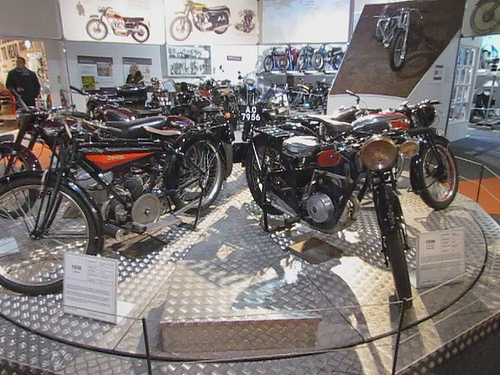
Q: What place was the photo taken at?
A: It was taken at the store.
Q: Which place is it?
A: It is a store.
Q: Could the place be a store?
A: Yes, it is a store.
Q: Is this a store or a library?
A: It is a store.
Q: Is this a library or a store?
A: It is a store.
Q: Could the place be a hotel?
A: No, it is a store.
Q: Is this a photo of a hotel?
A: No, the picture is showing a store.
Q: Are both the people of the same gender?
A: No, they are both male and female.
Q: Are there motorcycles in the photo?
A: Yes, there is a motorcycle.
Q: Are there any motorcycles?
A: Yes, there is a motorcycle.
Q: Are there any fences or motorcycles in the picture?
A: Yes, there is a motorcycle.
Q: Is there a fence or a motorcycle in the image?
A: Yes, there is a motorcycle.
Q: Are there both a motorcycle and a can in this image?
A: No, there is a motorcycle but no cans.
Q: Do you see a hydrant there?
A: No, there are no fire hydrants.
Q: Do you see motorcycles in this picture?
A: Yes, there is a motorcycle.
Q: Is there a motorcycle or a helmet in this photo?
A: Yes, there is a motorcycle.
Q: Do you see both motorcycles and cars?
A: No, there is a motorcycle but no cars.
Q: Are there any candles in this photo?
A: No, there are no candles.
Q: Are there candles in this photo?
A: No, there are no candles.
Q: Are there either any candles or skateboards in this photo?
A: No, there are no candles or skateboards.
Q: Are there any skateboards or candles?
A: No, there are no candles or skateboards.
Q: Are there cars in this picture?
A: No, there are no cars.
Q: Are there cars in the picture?
A: No, there are no cars.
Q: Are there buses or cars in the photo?
A: No, there are no cars or buses.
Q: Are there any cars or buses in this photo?
A: No, there are no cars or buses.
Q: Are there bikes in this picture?
A: Yes, there is a bike.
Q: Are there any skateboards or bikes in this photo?
A: Yes, there is a bike.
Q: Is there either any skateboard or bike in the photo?
A: Yes, there is a bike.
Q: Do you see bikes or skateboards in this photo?
A: Yes, there is a bike.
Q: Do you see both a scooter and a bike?
A: No, there is a bike but no scooters.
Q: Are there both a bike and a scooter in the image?
A: No, there is a bike but no scooters.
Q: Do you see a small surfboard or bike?
A: Yes, there is a small bike.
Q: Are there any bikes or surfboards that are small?
A: Yes, the bike is small.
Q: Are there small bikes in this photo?
A: Yes, there is a small bike.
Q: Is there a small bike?
A: Yes, there is a small bike.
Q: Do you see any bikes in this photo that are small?
A: Yes, there is a bike that is small.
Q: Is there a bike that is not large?
A: Yes, there is a small bike.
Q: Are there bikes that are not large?
A: Yes, there is a small bike.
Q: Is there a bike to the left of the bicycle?
A: Yes, there is a bike to the left of the bicycle.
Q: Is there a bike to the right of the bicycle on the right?
A: No, the bike is to the left of the bicycle.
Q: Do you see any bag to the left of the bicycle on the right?
A: No, there is a bike to the left of the bicycle.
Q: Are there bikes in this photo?
A: Yes, there is a bike.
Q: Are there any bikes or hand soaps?
A: Yes, there is a bike.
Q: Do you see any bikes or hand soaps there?
A: Yes, there is a bike.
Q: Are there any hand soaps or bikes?
A: Yes, there is a bike.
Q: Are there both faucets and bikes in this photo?
A: No, there is a bike but no faucets.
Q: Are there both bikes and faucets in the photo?
A: No, there is a bike but no faucets.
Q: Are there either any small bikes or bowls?
A: Yes, there is a small bike.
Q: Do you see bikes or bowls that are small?
A: Yes, the bike is small.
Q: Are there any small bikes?
A: Yes, there is a small bike.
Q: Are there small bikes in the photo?
A: Yes, there is a small bike.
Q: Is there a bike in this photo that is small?
A: Yes, there is a bike that is small.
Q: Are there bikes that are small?
A: Yes, there is a bike that is small.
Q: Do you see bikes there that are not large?
A: Yes, there is a small bike.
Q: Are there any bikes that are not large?
A: Yes, there is a small bike.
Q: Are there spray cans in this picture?
A: No, there are no spray cans.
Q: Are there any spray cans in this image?
A: No, there are no spray cans.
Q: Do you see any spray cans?
A: No, there are no spray cans.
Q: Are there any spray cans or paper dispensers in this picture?
A: No, there are no spray cans or paper dispensers.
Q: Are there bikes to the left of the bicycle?
A: Yes, there is a bike to the left of the bicycle.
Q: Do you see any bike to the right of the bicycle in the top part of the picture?
A: No, the bike is to the left of the bicycle.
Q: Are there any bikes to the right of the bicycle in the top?
A: No, the bike is to the left of the bicycle.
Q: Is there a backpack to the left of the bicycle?
A: No, there is a bike to the left of the bicycle.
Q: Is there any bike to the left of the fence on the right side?
A: Yes, there is a bike to the left of the fence.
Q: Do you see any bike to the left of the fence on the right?
A: Yes, there is a bike to the left of the fence.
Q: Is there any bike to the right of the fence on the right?
A: No, the bike is to the left of the fence.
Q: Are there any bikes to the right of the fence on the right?
A: No, the bike is to the left of the fence.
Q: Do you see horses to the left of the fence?
A: No, there is a bike to the left of the fence.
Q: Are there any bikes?
A: Yes, there is a bike.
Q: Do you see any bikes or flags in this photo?
A: Yes, there is a bike.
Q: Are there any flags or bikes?
A: Yes, there is a bike.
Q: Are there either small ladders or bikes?
A: Yes, there is a small bike.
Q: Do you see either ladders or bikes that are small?
A: Yes, the bike is small.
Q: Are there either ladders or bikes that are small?
A: Yes, the bike is small.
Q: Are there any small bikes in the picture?
A: Yes, there is a small bike.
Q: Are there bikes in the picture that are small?
A: Yes, there is a bike that is small.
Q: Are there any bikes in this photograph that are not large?
A: Yes, there is a small bike.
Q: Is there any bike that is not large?
A: Yes, there is a small bike.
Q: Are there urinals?
A: No, there are no urinals.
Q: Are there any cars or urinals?
A: No, there are no urinals or cars.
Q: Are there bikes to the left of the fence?
A: Yes, there is a bike to the left of the fence.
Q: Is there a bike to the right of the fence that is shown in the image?
A: No, the bike is to the left of the fence.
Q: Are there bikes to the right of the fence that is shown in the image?
A: No, the bike is to the left of the fence.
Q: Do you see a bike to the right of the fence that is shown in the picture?
A: No, the bike is to the left of the fence.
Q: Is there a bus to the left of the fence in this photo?
A: No, there is a bike to the left of the fence.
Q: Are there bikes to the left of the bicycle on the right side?
A: Yes, there is a bike to the left of the bicycle.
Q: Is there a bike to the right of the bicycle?
A: No, the bike is to the left of the bicycle.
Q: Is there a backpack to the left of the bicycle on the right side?
A: No, there is a bike to the left of the bicycle.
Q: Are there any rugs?
A: No, there are no rugs.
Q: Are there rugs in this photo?
A: No, there are no rugs.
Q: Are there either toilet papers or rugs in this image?
A: No, there are no rugs or toilet papers.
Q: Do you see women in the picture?
A: Yes, there is a woman.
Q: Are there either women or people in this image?
A: Yes, there is a woman.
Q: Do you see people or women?
A: Yes, there is a woman.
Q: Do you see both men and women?
A: Yes, there are both a woman and a man.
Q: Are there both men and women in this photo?
A: Yes, there are both a woman and a man.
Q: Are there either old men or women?
A: Yes, there is an old woman.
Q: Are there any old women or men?
A: Yes, there is an old woman.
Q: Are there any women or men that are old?
A: Yes, the woman is old.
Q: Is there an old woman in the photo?
A: Yes, there is an old woman.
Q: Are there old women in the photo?
A: Yes, there is an old woman.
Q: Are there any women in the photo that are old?
A: Yes, there is an old woman.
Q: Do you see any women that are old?
A: Yes, there is a woman that is old.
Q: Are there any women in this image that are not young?
A: Yes, there is a old woman.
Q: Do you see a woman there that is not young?
A: Yes, there is a old woman.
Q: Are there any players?
A: No, there are no players.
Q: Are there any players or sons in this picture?
A: No, there are no players or sons.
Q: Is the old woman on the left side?
A: Yes, the woman is on the left of the image.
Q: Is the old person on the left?
A: Yes, the woman is on the left of the image.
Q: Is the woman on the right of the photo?
A: No, the woman is on the left of the image.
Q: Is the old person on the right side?
A: No, the woman is on the left of the image.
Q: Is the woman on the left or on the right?
A: The woman is on the left of the image.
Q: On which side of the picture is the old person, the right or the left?
A: The woman is on the left of the image.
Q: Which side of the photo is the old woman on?
A: The woman is on the left of the image.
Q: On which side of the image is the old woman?
A: The woman is on the left of the image.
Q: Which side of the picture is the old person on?
A: The woman is on the left of the image.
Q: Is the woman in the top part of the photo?
A: Yes, the woman is in the top of the image.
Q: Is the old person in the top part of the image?
A: Yes, the woman is in the top of the image.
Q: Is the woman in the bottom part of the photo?
A: No, the woman is in the top of the image.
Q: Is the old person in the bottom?
A: No, the woman is in the top of the image.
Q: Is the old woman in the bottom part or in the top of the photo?
A: The woman is in the top of the image.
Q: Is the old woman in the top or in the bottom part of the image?
A: The woman is in the top of the image.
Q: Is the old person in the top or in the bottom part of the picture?
A: The woman is in the top of the image.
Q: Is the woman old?
A: Yes, the woman is old.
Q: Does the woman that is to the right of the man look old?
A: Yes, the woman is old.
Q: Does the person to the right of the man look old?
A: Yes, the woman is old.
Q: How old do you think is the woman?
A: The woman is old.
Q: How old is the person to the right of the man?
A: The woman is old.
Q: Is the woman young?
A: No, the woman is old.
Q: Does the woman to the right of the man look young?
A: No, the woman is old.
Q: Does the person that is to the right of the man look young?
A: No, the woman is old.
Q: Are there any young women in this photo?
A: No, there is a woman but she is old.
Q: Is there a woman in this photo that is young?
A: No, there is a woman but she is old.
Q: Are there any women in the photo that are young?
A: No, there is a woman but she is old.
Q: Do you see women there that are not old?
A: No, there is a woman but she is old.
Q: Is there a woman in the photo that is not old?
A: No, there is a woman but she is old.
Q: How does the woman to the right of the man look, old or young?
A: The woman is old.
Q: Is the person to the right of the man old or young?
A: The woman is old.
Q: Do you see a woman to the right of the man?
A: Yes, there is a woman to the right of the man.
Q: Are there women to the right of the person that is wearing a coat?
A: Yes, there is a woman to the right of the man.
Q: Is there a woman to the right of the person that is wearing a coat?
A: Yes, there is a woman to the right of the man.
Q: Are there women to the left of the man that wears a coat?
A: No, the woman is to the right of the man.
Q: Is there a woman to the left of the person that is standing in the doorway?
A: No, the woman is to the right of the man.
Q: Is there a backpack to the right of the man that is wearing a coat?
A: No, there is a woman to the right of the man.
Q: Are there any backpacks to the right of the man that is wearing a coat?
A: No, there is a woman to the right of the man.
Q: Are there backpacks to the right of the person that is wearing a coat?
A: No, there is a woman to the right of the man.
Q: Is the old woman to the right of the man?
A: Yes, the woman is to the right of the man.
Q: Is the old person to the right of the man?
A: Yes, the woman is to the right of the man.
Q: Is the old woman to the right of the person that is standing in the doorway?
A: Yes, the woman is to the right of the man.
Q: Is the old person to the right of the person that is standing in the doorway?
A: Yes, the woman is to the right of the man.